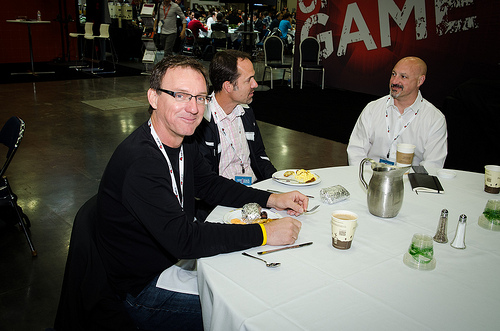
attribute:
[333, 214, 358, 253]
cup — brown, white